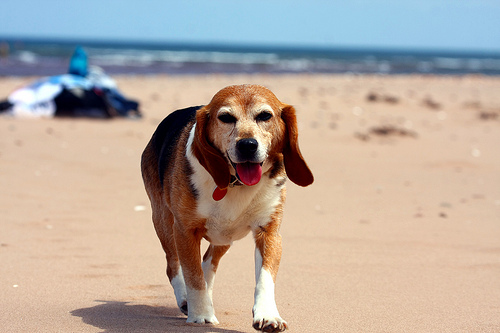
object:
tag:
[211, 170, 243, 201]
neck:
[197, 97, 286, 184]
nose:
[236, 138, 258, 155]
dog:
[172, 84, 404, 316]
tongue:
[234, 163, 264, 186]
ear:
[279, 105, 314, 187]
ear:
[191, 108, 232, 189]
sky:
[195, 0, 445, 40]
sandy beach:
[3, 69, 497, 331]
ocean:
[6, 35, 498, 75]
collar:
[230, 178, 239, 187]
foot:
[253, 307, 288, 331]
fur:
[258, 277, 273, 315]